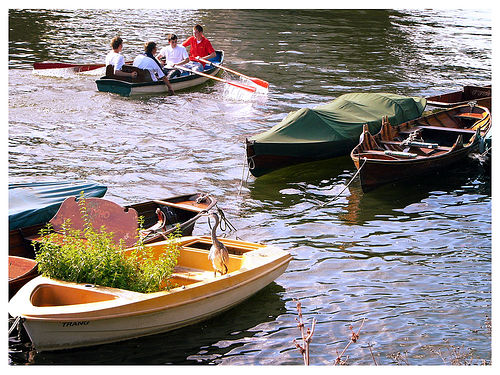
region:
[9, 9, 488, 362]
a body of water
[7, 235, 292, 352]
a yellow and cream boat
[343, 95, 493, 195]
a brown wooden boat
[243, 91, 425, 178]
a green covered boat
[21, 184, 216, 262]
a brown boat in water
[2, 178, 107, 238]
a green covered boat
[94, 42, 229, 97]
a white and green boat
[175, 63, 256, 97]
a long red oar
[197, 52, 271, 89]
a long red oar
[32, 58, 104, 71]
a long red oar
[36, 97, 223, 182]
The water on the lake is calm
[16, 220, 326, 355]
The boat is small and beige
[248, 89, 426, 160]
The boat cover is green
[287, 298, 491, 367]
The branches are brown with no leaves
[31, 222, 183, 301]
The plants in the boat are green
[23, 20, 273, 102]
A group in a boat paddling forward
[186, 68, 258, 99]
The paddle is brown and road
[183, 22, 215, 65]
The shirt on the boy is red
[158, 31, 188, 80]
The boy is wearing a white shirt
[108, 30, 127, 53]
The head of a boy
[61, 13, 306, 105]
guys in a row boat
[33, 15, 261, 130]
four guys rowing a boat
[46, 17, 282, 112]
four guys paddling a boat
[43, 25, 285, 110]
a paddle boat in a lake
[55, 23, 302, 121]
a row boat in a lake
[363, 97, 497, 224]
an empty canoe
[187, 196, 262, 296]
a bird standing in a boat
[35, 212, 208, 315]
a bush growing in a boat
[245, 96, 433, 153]
a canoe covered with a tarp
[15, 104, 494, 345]
boats tied down and docked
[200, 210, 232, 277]
Bird standing in boat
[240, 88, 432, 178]
Green cover over boat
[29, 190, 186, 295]
Foliage inside boat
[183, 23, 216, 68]
Man in red shirt is rowing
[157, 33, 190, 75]
Man in white shirt sitting in front of man in red shirt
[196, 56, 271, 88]
Long wooden oar is wet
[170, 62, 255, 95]
Long wooden oar is wet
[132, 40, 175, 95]
Man sticking hand in water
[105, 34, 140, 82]
Man has arm behind man in white shirt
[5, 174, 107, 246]
Blue cover cowering boat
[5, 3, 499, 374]
several boats in a blue lake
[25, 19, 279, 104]
a family using a rowboat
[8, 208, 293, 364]
a white boat with a green plant in it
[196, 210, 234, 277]
a grey and white heron in a boat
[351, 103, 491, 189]
a rowboat with a wooden interior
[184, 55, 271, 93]
two oars with red paddles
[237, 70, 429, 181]
a blue boat with a green cover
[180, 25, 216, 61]
a man wearing a red polo shirt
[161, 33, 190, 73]
a boy wearing a white t-shirt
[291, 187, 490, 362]
blue and green water with ripples